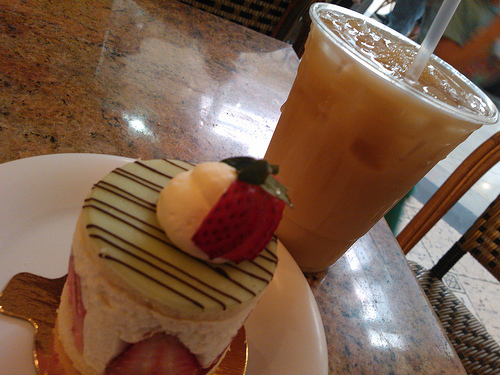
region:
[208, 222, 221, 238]
a seed of a strawberry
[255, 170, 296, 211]
a green strawberry leaf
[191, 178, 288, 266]
red strawberry slices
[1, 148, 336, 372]
a white plate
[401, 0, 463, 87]
a clear drinking straw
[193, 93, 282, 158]
light shining on the table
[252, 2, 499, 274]
a cup filled with liquid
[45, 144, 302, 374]
a dessert on the plate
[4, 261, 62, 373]
a brown sauce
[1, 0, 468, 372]
a marble counter top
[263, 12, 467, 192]
the ice tea is full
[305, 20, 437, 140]
the ice tea is full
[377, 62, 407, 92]
edge of a cup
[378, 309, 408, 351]
part of a table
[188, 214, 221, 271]
part of a cream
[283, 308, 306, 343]
part of a plate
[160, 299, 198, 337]
part of an edge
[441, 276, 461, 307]
part of a chair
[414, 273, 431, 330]
edge of a table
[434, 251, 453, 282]
part of a stand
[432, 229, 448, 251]
part of a floor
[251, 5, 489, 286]
A beige drink in a clear cup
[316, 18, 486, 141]
There is a clear straw in the drink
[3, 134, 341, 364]
A white, round plate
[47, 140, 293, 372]
A white, brown, and green pastry with strawberries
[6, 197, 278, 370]
The pastry is on a gold platter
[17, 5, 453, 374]
Brown and black granite counter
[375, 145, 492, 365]
Brown and black chair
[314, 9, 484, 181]
There is ice cubes in the drink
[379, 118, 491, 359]
The flooring is black and brown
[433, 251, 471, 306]
A small square design in the flooring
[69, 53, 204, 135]
brown granite top table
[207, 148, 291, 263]
a piece of a strawberry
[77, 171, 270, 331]
a green and brown cookie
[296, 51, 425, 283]
a plastic cup sweating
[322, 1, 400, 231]
an orange beverage inside the cup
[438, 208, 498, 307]
a brown and black wicker chair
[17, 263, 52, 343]
a gold small foil tray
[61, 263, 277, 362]
a cylinder appetizer dish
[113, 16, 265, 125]
a reflection of the sunlight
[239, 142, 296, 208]
a small green leaf